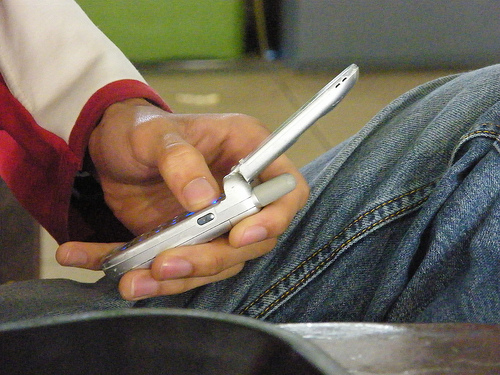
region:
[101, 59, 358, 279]
A silver cell phone.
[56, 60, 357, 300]
A hand holding a cell phone.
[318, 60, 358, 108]
The top of the phone.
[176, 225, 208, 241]
Part of the side of the phone.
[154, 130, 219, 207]
The person's thumb.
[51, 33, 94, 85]
Part of a sleeve.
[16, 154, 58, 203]
Part of the dark red sleeve.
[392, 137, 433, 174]
Part of the jeans.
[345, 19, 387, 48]
Part of the wall.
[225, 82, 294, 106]
Part of the ground.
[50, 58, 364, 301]
Cell phone in the hand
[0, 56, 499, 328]
Fading pair of jeans pants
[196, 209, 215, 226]
Silver button on the phone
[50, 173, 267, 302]
Fingers with short nails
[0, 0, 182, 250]
Red and white colored sleeve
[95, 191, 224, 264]
Blue light emanating from the keypad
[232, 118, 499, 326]
Hemming line on the cloth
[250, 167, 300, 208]
Short stumpy grey aerial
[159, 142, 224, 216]
Finger on a button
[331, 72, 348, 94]
Titny openings at the top of a cell phone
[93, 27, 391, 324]
the man is holding his cell phone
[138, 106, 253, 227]
the man is pushing a button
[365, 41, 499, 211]
the man is wearing jeans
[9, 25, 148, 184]
the man's shirt is red and white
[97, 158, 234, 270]
the buttons are lit up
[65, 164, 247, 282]
the buttons are blue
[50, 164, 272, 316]
the man has big fingers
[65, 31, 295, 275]
the man is white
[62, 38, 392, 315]
this is a flip phone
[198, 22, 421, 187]
the top part of the phone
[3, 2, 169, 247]
a red and white colored sleeve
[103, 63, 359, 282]
a silver colored cellphone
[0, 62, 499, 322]
blue jean pants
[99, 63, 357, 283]
the cellphone is a flip phone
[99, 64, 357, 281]
the silver cellphone has blue buttons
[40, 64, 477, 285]
a tan colored floor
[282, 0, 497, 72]
a gray colored wall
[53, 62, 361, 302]
a person's left hand holding the cellphone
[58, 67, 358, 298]
a person using their thumb to press buttons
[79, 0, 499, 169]
blurred background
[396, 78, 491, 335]
A pair of blue denim jeans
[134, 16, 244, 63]
A green stand in a hallway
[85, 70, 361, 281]
An old Grey flip phone in his hand.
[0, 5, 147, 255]
A red and white sweater.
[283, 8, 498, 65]
The wall is painted Grey .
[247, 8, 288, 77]
A broom that is standing in the wallway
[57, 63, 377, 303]
A man holding a cell phone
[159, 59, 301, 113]
Brown title on the floor.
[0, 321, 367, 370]
A dark Brown basket on a table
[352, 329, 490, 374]
A dark brown table